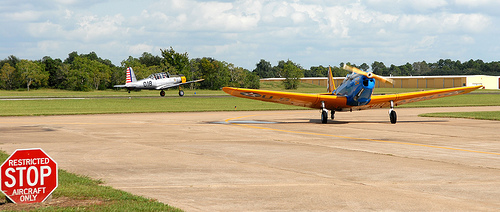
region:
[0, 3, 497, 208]
private plane on tarmac at small rural airport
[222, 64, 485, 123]
yellow and blue propeller plane taxiing on runway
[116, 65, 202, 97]
plane landing at small rural airport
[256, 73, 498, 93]
rural airport hangar building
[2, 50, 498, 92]
windbreak trees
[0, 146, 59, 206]
RESTRICTED STOP AIRCRAFT ONLY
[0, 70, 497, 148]
fky full of fluffy clouds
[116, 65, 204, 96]
old fashioned Navy training plane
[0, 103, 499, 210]
airport taxiways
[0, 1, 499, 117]
high white clouds in a summer sky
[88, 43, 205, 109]
a plane in road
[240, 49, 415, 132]
a plane in ground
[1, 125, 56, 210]
a board in grass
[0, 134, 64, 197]
a board in ground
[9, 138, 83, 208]
a board in earth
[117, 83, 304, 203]
a clean view of sand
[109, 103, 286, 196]
a clean view of ground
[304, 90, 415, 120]
wheel of the plane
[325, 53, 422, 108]
fan in front of plane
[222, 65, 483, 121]
a plane taking off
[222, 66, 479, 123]
plane is yellow and blue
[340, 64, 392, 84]
the propeller is spinning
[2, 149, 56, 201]
sign is red and white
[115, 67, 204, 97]
a plane is parked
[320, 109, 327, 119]
the wheel is black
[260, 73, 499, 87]
hangar in the distance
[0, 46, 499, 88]
a line of trees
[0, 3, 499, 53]
clouds fill the sky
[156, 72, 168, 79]
canopy of the plane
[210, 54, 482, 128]
plane on the tarmac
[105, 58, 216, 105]
plane on the runway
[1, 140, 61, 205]
red and white sign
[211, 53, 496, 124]
blue and yellow plane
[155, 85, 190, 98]
a pair of wheels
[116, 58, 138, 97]
tail of the plane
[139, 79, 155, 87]
black writing on the side of the plane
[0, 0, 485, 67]
thick clouds in the sky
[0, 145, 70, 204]
sign on the ground